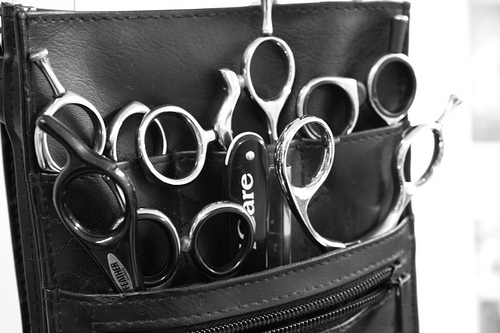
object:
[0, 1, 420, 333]
holder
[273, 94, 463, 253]
scissors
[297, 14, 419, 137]
scissors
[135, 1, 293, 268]
scissors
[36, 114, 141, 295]
scissors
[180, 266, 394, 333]
zipper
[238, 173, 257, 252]
text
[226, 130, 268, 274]
object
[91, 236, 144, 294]
handle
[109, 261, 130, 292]
text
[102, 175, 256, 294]
scissors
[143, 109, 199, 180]
finger hole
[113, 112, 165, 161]
finger hole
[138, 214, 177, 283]
finger hole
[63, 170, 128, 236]
finger hole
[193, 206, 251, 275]
finger hole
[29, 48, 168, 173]
scissors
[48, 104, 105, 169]
finger hole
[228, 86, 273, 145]
finger hole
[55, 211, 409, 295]
slot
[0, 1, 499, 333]
background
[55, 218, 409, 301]
edge